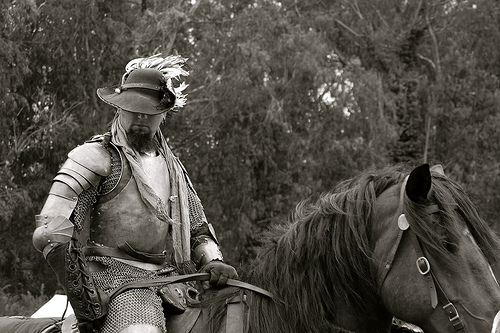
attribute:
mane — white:
[188, 160, 498, 332]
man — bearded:
[29, 44, 243, 331]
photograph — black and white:
[3, 3, 499, 331]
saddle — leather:
[163, 276, 249, 331]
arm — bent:
[31, 155, 106, 331]